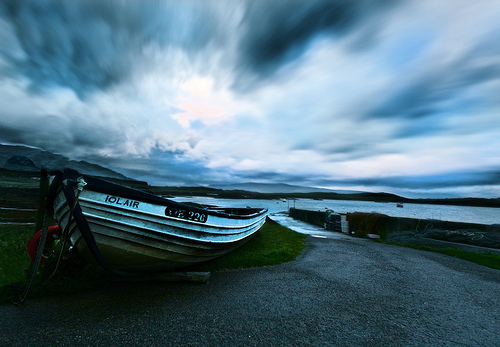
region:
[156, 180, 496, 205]
a hill on the background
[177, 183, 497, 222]
a lake in front the hills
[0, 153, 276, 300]
a boat behind a car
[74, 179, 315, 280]
a boat over green gras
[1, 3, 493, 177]
sky is very cloudy with black clouds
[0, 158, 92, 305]
the truck is green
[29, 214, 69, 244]
a red light on back a car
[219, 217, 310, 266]
green grass under a boat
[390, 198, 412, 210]
a bot in the water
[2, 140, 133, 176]
a rocky mountain on the background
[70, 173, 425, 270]
a white boat in front the water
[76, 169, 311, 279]
the boat is on field of green grass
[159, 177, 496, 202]
hills on the background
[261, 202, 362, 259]
a path next green grass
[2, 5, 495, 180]
the sky is overcast with black clouds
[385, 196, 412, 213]
a boat in the body of water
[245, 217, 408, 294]
green grass near a road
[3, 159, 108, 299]
boat is attached to a car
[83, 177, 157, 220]
the nose of boat has a letter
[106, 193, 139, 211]
the black painted letters on a boar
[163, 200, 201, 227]
a white set of numbers on a boat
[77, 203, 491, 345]
a wet dirt road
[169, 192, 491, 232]
a large grey blue body of water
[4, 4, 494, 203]
a grey overcast sky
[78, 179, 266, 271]
a dirty white wooden boat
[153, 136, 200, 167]
a fluffy white cloud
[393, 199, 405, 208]
a black boat out in the water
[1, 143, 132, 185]
a mountain range in the background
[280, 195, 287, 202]
a white boat in the water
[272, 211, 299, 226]
boat dock to lake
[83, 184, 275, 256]
white boat on green grass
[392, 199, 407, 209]
boat on water in the distance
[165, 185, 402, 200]
hillside in the distance of lake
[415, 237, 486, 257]
small concrete wall by lake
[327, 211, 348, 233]
white container by boat ramp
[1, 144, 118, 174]
grey mountains behind the boat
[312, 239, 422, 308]
grey gravel road in front of boat ramp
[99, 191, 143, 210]
name of white boat in black letters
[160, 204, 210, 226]
licence number of white boat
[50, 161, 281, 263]
a boat ready for launch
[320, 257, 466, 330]
gravel road leading to water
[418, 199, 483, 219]
a body of water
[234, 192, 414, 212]
boats out on the water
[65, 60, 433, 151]
ominous clouds in the sky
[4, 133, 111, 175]
rolling hills leading to water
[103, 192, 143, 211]
name of the boat painted on its side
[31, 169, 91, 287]
part of a boat hitch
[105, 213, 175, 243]
white painted siding of a small boat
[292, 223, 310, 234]
puddles in the roadway